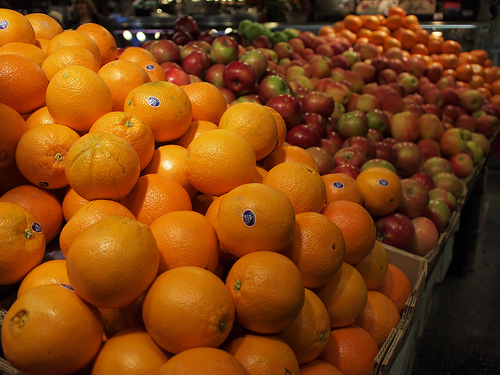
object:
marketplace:
[3, 1, 480, 372]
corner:
[0, 293, 109, 375]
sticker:
[242, 208, 256, 228]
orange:
[218, 182, 296, 259]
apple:
[337, 110, 370, 138]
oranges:
[0, 7, 407, 375]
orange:
[65, 130, 140, 200]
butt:
[89, 138, 111, 157]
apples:
[141, 14, 499, 253]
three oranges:
[66, 208, 234, 353]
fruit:
[0, 3, 496, 375]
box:
[373, 254, 433, 373]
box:
[427, 188, 476, 311]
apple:
[287, 123, 320, 148]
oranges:
[318, 1, 500, 105]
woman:
[71, 1, 101, 26]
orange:
[2, 282, 105, 373]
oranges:
[355, 167, 401, 216]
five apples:
[239, 18, 297, 43]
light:
[430, 31, 444, 36]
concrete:
[418, 163, 497, 375]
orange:
[428, 38, 442, 53]